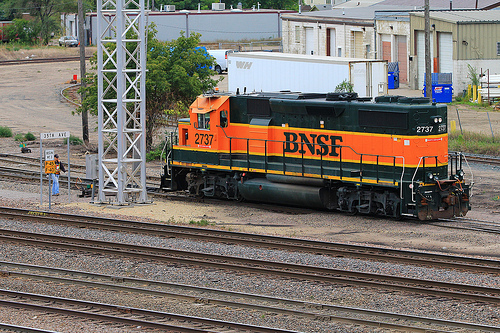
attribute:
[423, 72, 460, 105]
dumpster — blue , trash dumpster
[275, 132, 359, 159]
letter — black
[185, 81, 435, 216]
train — orange, black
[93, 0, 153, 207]
structure — tall, white, metal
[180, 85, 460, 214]
train — black, orange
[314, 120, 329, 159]
letter — black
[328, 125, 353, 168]
letter — black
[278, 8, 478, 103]
garages — closed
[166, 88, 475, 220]
train car — dark, black, orange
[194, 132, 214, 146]
number — black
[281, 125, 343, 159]
logo — BNSF logo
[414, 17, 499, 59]
building — brown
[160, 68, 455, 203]
train — orange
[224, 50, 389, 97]
trailer — white, tractor trailer, behind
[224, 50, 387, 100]
truck — large, white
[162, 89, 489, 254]
car — silver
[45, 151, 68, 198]
person — walking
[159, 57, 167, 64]
leaves — green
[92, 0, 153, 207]
tower — tall, white, metal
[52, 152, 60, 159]
cap — black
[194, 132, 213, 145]
number — painted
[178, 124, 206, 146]
number — black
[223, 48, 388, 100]
cargo container — white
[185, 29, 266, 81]
van — white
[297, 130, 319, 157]
letter — black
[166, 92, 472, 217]
railcar — black, orange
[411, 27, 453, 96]
garage — white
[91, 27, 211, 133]
tree — green